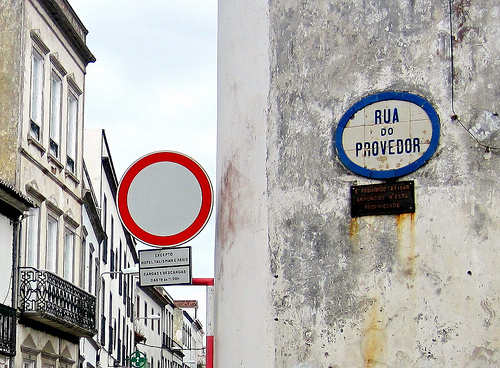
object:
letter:
[395, 136, 403, 154]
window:
[43, 197, 63, 276]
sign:
[124, 341, 151, 366]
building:
[33, 68, 225, 364]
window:
[34, 70, 82, 168]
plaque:
[320, 82, 435, 177]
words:
[327, 82, 469, 184]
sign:
[296, 60, 467, 187]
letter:
[358, 136, 375, 168]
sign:
[350, 181, 416, 216]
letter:
[368, 100, 383, 130]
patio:
[11, 263, 143, 338]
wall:
[202, 75, 498, 368]